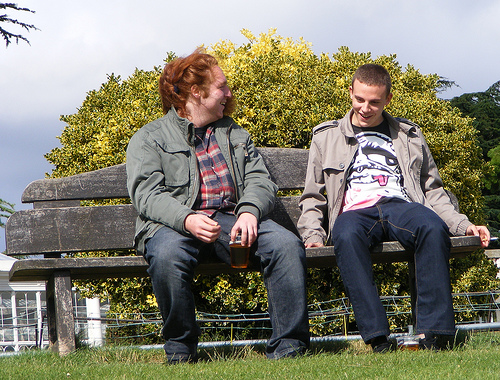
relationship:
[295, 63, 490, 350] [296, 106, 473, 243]
man wearing jacket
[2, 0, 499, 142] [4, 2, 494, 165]
clouds in sky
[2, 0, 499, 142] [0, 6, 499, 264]
clouds in sky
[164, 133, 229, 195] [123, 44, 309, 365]
shirt on person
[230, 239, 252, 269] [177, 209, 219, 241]
drink in hand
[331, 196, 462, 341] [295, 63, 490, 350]
jeans on man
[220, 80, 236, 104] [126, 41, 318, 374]
nose of man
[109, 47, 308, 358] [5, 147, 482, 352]
person on wooden bench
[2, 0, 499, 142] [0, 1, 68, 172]
clouds in sky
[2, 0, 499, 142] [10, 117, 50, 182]
clouds in blue sky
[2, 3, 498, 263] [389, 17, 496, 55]
clouds in sky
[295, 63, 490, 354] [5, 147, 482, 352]
man sitting on wooden bench